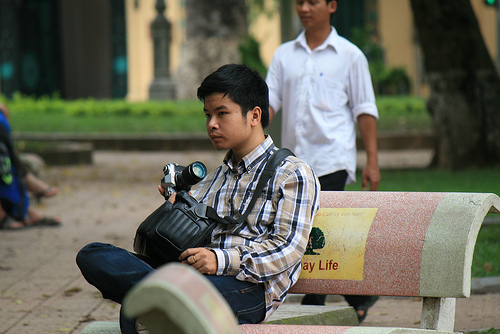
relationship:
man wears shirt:
[258, 0, 383, 188] [263, 27, 381, 179]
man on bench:
[65, 56, 324, 324] [116, 183, 499, 333]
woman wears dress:
[4, 104, 67, 234] [4, 120, 37, 224]